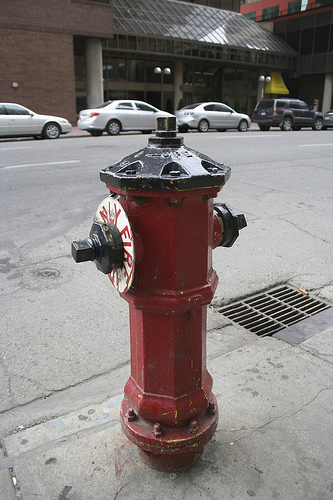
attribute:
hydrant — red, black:
[71, 116, 250, 471]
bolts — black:
[70, 204, 248, 276]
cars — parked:
[1, 98, 331, 139]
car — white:
[74, 98, 179, 135]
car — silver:
[174, 102, 252, 133]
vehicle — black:
[252, 96, 327, 132]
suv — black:
[249, 98, 327, 131]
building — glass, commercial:
[1, 1, 297, 135]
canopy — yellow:
[265, 69, 293, 98]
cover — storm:
[214, 277, 330, 340]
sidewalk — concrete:
[2, 120, 331, 139]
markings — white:
[5, 158, 85, 168]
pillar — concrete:
[80, 37, 108, 109]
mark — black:
[47, 454, 58, 467]